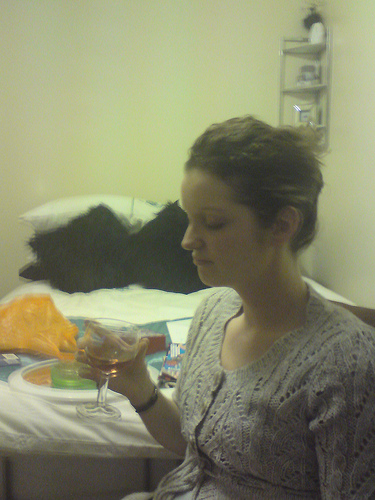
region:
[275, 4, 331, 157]
a corner shelf with knick knacks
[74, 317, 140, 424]
a half full wine glass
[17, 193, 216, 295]
a pile of pillows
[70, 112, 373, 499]
a woman drinking from a glass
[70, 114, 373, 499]
a woman in a grey sweater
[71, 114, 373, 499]
a woman with short brown hair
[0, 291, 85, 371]
a crumpled yellow bag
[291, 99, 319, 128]
yellow picture frame on shelf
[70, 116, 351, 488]
woman in grey shirt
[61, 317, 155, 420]
wine glass in right hand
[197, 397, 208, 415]
plastic button on grey shirt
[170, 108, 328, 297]
woman with hair put up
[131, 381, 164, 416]
black watch on right wrist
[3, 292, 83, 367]
orange plastic bag on bed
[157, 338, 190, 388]
book behind woman in grey shirt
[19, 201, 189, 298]
black fur pillows on bed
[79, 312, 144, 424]
clear glass with wine in it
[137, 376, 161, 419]
black bracelette on girls arm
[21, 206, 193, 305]
black pillows on her bed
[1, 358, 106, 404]
white tray on the bed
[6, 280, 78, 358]
yellow plastic bag on the bed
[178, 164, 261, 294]
girls face looking at the wine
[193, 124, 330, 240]
browm hair on her head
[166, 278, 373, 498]
gray sweater that she is wearing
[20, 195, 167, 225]
white pillow on top of the black ones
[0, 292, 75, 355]
YELLOW BAG ON THE BED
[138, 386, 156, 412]
WATCH ON THE WRIST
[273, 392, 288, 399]
HOLES IN THE SWEATER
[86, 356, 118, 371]
WINE IN THE GLASS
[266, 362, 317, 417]
WOMAN WEARING GREY SWEATER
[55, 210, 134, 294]
BLACK FURY PILLOWS ON THE BED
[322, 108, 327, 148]
IRON RACK SHELF IN THE CORNER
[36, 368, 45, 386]
TRAY ON THE BED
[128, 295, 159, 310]
WHITE SHEETS ON THE BED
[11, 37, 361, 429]
this is a woman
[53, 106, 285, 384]
the woman is alone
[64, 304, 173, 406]
the glass is large